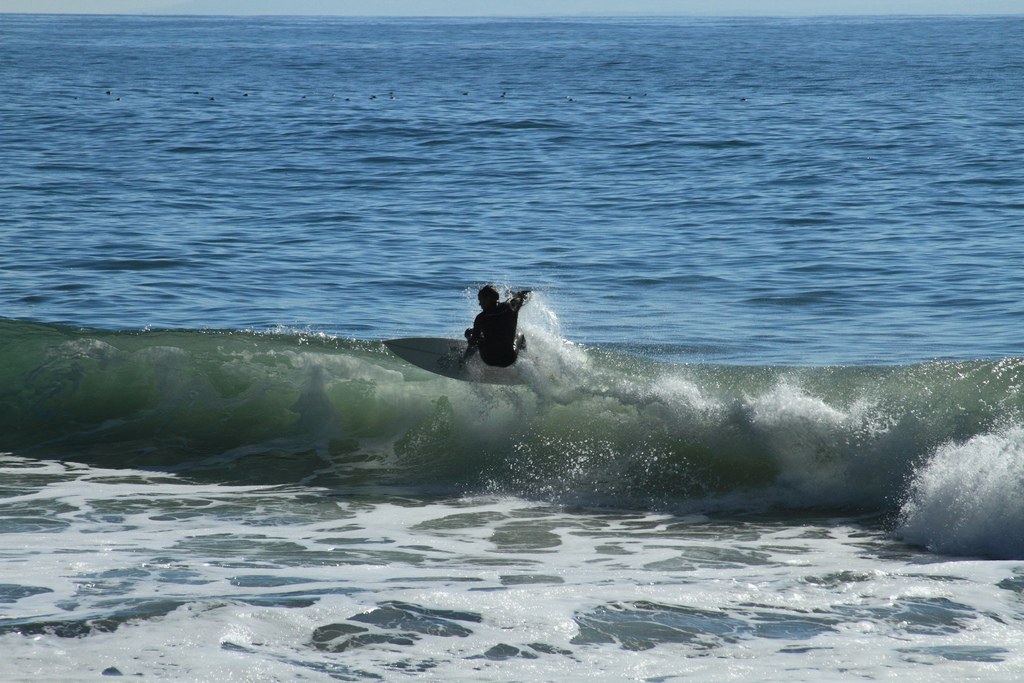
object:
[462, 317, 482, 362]
arm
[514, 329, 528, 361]
leg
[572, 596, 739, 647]
water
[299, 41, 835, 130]
birds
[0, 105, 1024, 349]
waves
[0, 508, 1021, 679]
sea foam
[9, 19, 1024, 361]
water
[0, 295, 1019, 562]
wave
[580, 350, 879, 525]
water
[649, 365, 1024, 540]
wave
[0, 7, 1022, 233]
ocean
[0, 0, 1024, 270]
water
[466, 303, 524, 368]
black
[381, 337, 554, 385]
surfboard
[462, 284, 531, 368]
man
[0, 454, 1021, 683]
part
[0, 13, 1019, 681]
water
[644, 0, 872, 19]
patch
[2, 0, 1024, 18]
sky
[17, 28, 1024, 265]
water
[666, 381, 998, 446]
top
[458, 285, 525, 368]
surfer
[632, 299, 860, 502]
water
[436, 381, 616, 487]
ocean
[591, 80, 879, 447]
ocean